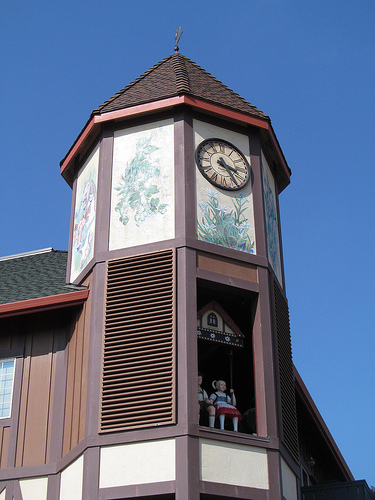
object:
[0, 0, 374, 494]
sky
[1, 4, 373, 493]
view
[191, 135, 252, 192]
clock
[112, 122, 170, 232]
design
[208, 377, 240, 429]
girl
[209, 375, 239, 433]
doll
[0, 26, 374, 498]
building